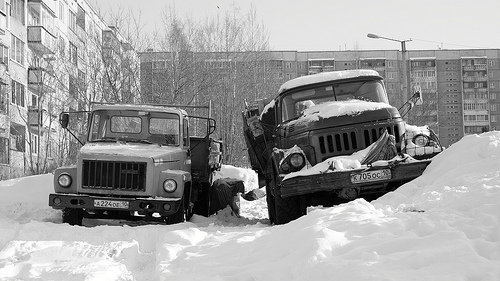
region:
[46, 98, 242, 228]
white pick up truck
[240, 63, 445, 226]
black pick up truck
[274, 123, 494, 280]
mountain of snow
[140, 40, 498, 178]
tall concrete building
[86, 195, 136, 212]
black and white license plate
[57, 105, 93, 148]
extended side view mirror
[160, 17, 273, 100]
trees bare of leaves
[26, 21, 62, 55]
balcony on side of building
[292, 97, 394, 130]
snow on hood of truck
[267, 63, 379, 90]
snow on roof of truck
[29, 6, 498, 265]
vehicles parked on the snow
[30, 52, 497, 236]
vehicles parked outside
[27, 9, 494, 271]
vehicles with snow on them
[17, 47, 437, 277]
trucks parked in snow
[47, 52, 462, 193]
trucks parked on white snow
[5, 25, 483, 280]
two trucks parked on snow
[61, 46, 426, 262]
two trucks parked on white snow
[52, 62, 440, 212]
two trucks covered in snow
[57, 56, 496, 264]
snow on two trucks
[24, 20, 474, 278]
trucks covered with snow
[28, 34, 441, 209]
2 old trucks in snow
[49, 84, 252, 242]
old grey truck in snow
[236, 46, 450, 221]
old black volvo truck covered in snow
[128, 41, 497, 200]
large apartment building in background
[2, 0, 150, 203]
apartment building with balconies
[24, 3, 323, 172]
large trees with no leaves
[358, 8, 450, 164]
street light in background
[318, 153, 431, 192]
license plate reading "k705oc"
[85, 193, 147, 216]
license plate reading "a2240"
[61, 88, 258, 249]
grey truck with old flat bed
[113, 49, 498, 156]
a building with balconies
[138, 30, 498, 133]
balconies on a building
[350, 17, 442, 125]
a street light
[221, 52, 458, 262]
a old vehicle parked on snow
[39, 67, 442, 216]
two old vehicles parked on snow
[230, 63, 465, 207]
a old vehicle with snow on it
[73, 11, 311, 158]
trees with no leaves on them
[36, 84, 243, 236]
a old vehicle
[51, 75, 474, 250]
two old vehicles with snow on them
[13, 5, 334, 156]
two buildings with balconies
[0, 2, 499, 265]
Taken in black and white.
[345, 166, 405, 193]
License plate on the truck.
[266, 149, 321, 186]
Light on the truck.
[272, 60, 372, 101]
Snow on the truck.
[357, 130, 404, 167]
Trash on the truck.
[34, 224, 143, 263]
Shadow on the ground.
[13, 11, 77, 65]
Balcony on the building.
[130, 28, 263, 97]
No leaves on the tree.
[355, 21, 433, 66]
Light on a pole.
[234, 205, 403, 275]
Snow on the ground.